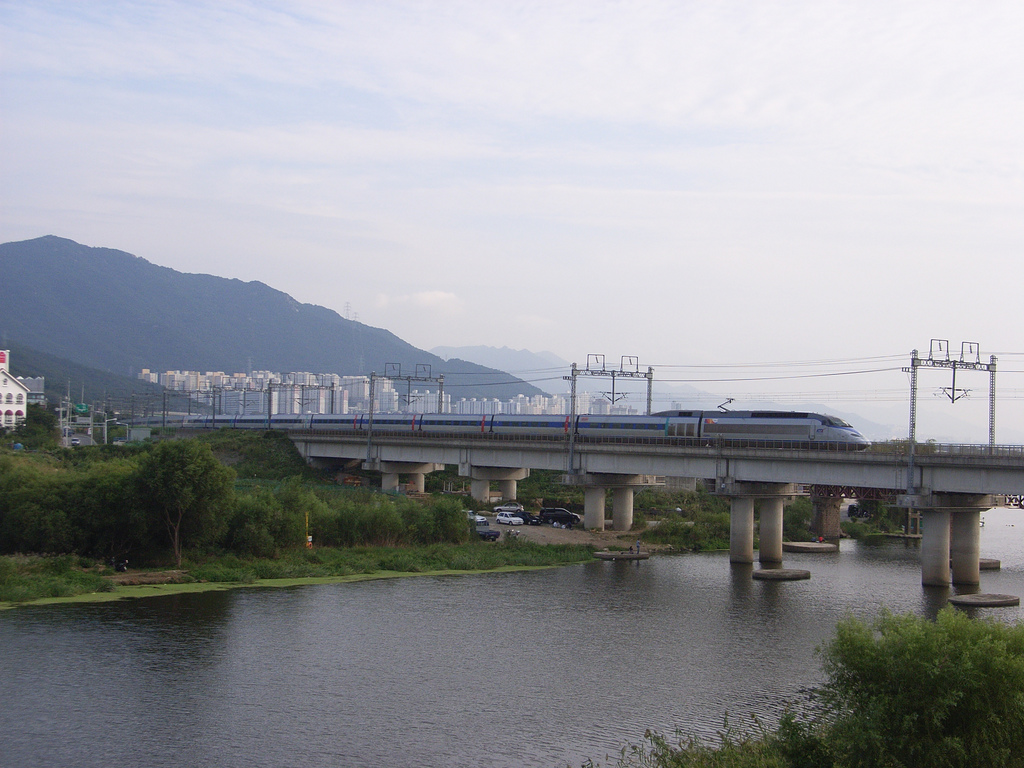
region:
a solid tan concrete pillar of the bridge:
[377, 471, 397, 494]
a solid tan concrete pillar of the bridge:
[406, 469, 423, 492]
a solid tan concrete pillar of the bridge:
[494, 474, 517, 504]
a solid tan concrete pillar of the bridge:
[582, 486, 603, 534]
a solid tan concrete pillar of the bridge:
[612, 478, 633, 526]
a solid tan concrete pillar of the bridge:
[727, 493, 751, 564]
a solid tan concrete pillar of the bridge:
[917, 510, 950, 590]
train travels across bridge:
[138, 405, 873, 448]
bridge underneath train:
[280, 434, 1023, 591]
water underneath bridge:
[0, 504, 1021, 764]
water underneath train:
[0, 503, 1019, 759]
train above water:
[162, 411, 867, 451]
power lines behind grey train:
[141, 339, 1023, 439]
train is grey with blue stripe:
[127, 409, 871, 454]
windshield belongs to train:
[820, 417, 850, 430]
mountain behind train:
[1, 229, 551, 397]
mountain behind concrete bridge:
[2, 229, 554, 397]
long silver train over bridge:
[310, 391, 876, 449]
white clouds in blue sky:
[431, 127, 489, 170]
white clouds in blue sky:
[699, 54, 783, 118]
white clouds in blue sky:
[514, 192, 622, 269]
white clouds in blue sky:
[336, 110, 406, 174]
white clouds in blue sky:
[468, 130, 561, 198]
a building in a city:
[157, 364, 186, 393]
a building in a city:
[217, 368, 244, 411]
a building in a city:
[266, 371, 290, 407]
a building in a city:
[319, 380, 346, 413]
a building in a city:
[369, 374, 388, 416]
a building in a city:
[388, 371, 407, 413]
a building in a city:
[407, 386, 428, 409]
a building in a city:
[438, 377, 457, 413]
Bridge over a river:
[0, 362, 1015, 765]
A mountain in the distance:
[0, 215, 557, 419]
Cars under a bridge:
[119, 354, 1021, 615]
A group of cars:
[448, 484, 586, 543]